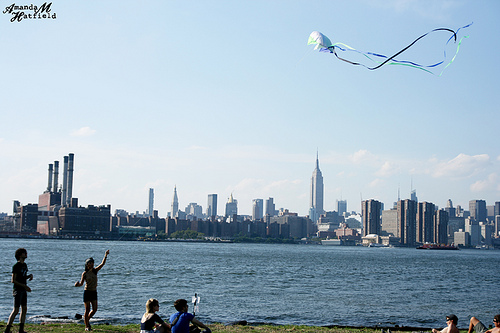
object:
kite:
[305, 23, 476, 76]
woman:
[75, 250, 111, 332]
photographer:
[0, 1, 62, 22]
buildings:
[396, 199, 418, 244]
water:
[0, 236, 500, 326]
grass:
[214, 317, 402, 333]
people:
[133, 300, 169, 332]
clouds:
[322, 126, 491, 198]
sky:
[6, 7, 488, 201]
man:
[166, 297, 216, 332]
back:
[169, 313, 188, 333]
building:
[306, 147, 327, 218]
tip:
[314, 145, 321, 162]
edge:
[320, 176, 326, 201]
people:
[3, 245, 35, 329]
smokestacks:
[46, 162, 53, 192]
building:
[35, 153, 109, 235]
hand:
[105, 250, 110, 255]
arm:
[94, 253, 109, 272]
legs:
[83, 299, 90, 327]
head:
[173, 299, 190, 314]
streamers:
[326, 22, 473, 78]